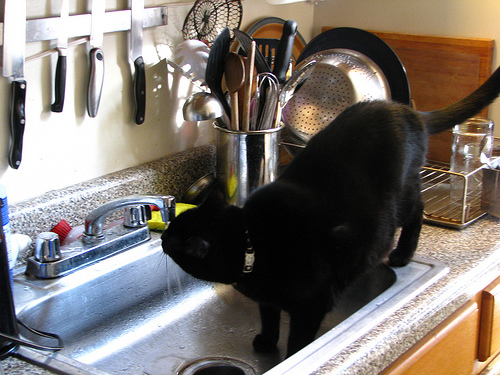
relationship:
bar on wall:
[0, 1, 170, 51] [6, 2, 312, 207]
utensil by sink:
[253, 70, 283, 129] [6, 194, 448, 373]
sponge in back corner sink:
[149, 200, 194, 230] [6, 194, 448, 373]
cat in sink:
[152, 65, 500, 363] [6, 194, 448, 373]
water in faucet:
[159, 261, 188, 324] [77, 188, 180, 242]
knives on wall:
[1, 3, 166, 170] [4, 6, 220, 189]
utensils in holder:
[199, 12, 302, 128] [215, 126, 285, 198]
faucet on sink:
[77, 188, 180, 242] [6, 194, 448, 373]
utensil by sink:
[237, 34, 260, 135] [6, 194, 448, 373]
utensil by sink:
[268, 12, 298, 132] [6, 194, 448, 373]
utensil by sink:
[201, 21, 239, 126] [6, 194, 448, 373]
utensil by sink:
[253, 64, 282, 129] [6, 194, 448, 373]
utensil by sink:
[179, 86, 231, 131] [6, 194, 448, 373]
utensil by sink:
[124, 3, 153, 128] [6, 194, 448, 373]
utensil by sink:
[79, 3, 109, 123] [6, 194, 448, 373]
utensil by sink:
[42, 4, 71, 114] [6, 194, 448, 373]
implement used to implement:
[1, 1, 31, 173] [1, 1, 31, 170]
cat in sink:
[152, 75, 483, 357] [6, 194, 448, 373]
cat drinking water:
[152, 75, 483, 357] [160, 240, 180, 286]